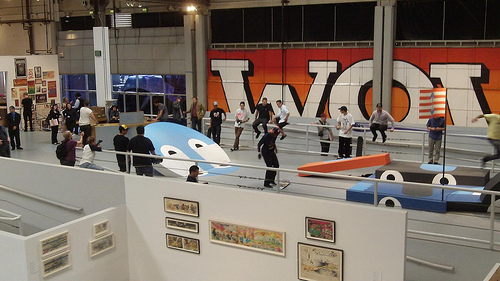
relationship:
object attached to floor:
[132, 120, 237, 182] [3, 105, 498, 214]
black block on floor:
[373, 156, 487, 186] [283, 165, 355, 197]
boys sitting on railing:
[366, 102, 394, 142] [200, 104, 493, 168]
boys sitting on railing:
[272, 100, 289, 136] [200, 104, 493, 168]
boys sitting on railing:
[251, 97, 276, 134] [200, 104, 493, 168]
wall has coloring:
[208, 42, 499, 128] [203, 43, 497, 127]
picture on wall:
[163, 196, 200, 217] [119, 173, 410, 279]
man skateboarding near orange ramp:
[257, 127, 282, 189] [297, 152, 391, 177]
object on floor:
[143, 121, 240, 177] [3, 121, 498, 277]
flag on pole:
[415, 86, 448, 118] [440, 86, 450, 179]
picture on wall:
[13, 57, 28, 81] [1, 52, 62, 124]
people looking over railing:
[78, 135, 103, 170] [73, 144, 499, 256]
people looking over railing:
[58, 127, 85, 166] [73, 144, 499, 256]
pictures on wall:
[13, 57, 31, 79] [14, 60, 56, 93]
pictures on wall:
[16, 82, 33, 93] [14, 60, 56, 93]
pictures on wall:
[35, 72, 46, 87] [14, 60, 56, 93]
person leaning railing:
[225, 89, 265, 159] [192, 115, 453, 173]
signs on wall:
[9, 57, 57, 107] [3, 43, 66, 139]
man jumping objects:
[471, 84, 498, 171] [344, 162, 499, 215]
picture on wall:
[158, 194, 204, 221] [2, 151, 412, 277]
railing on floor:
[70, 143, 496, 268] [3, 121, 498, 277]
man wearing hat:
[106, 110, 136, 158] [114, 117, 132, 129]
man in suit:
[2, 102, 28, 155] [124, 123, 157, 176]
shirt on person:
[335, 115, 356, 140] [331, 97, 364, 169]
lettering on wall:
[208, 55, 494, 127] [208, 42, 499, 128]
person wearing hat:
[114, 125, 129, 168] [114, 125, 131, 133]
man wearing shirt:
[56, 94, 96, 139] [48, 96, 86, 133]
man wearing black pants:
[257, 127, 282, 189] [259, 151, 285, 191]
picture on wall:
[33, 63, 43, 83] [3, 49, 65, 130]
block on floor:
[295, 145, 393, 177] [16, 190, 496, 279]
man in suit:
[247, 124, 294, 194] [122, 137, 170, 173]